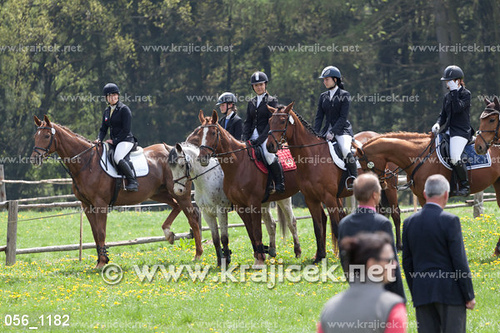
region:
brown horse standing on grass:
[33, 80, 178, 270]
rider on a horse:
[94, 73, 143, 198]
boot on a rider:
[117, 148, 139, 195]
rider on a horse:
[435, 63, 475, 190]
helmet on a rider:
[440, 60, 470, 91]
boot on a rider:
[452, 153, 474, 199]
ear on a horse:
[280, 100, 293, 118]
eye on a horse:
[274, 114, 287, 125]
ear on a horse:
[172, 135, 187, 162]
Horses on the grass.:
[26, 57, 425, 301]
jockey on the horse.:
[66, 69, 177, 197]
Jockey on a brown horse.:
[73, 67, 225, 261]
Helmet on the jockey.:
[72, 54, 143, 175]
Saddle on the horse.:
[71, 117, 165, 202]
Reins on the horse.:
[13, 80, 108, 197]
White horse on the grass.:
[150, 118, 265, 275]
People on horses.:
[200, 52, 458, 237]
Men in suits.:
[308, 165, 433, 316]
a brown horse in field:
[29, 113, 206, 270]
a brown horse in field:
[192, 109, 344, 269]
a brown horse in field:
[262, 99, 407, 266]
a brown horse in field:
[350, 123, 498, 263]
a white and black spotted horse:
[162, 141, 302, 271]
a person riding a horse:
[31, 81, 204, 273]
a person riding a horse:
[169, 91, 304, 265]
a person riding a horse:
[196, 71, 341, 269]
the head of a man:
[91, 81, 125, 118]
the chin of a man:
[103, 93, 128, 113]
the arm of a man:
[105, 104, 145, 161]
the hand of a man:
[104, 130, 114, 157]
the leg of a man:
[111, 171, 158, 205]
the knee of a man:
[110, 147, 142, 196]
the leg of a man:
[105, 132, 147, 174]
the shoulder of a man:
[111, 98, 138, 126]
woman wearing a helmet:
[16, 75, 172, 225]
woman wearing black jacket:
[25, 75, 146, 215]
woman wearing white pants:
[35, 73, 156, 205]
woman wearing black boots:
[90, 76, 157, 202]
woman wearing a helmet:
[426, 65, 482, 170]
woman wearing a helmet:
[310, 63, 362, 163]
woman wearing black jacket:
[300, 52, 360, 167]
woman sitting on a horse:
[75, 75, 146, 200]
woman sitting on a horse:
[316, 62, 359, 163]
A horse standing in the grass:
[27, 113, 202, 265]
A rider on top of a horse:
[97, 80, 139, 192]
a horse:
[28, 114, 204, 262]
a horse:
[156, 132, 305, 255]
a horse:
[197, 123, 335, 256]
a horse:
[269, 101, 408, 244]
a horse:
[354, 117, 496, 264]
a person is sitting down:
[98, 80, 146, 190]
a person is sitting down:
[211, 90, 241, 135]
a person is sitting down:
[243, 67, 296, 192]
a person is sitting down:
[313, 69, 363, 191]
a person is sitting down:
[428, 62, 475, 194]